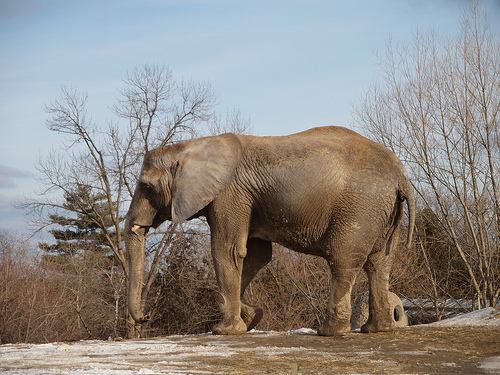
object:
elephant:
[123, 125, 416, 336]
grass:
[285, 341, 356, 368]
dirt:
[170, 335, 250, 350]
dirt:
[26, 341, 76, 360]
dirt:
[137, 353, 215, 374]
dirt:
[227, 337, 319, 369]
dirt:
[306, 349, 370, 369]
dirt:
[205, 353, 297, 371]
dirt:
[57, 340, 121, 350]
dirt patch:
[423, 333, 489, 354]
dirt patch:
[154, 363, 194, 367]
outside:
[1, 0, 500, 375]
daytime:
[283, 1, 413, 27]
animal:
[123, 125, 414, 337]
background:
[0, 59, 500, 346]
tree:
[9, 60, 222, 339]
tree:
[344, 0, 500, 309]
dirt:
[397, 327, 500, 338]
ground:
[0, 307, 498, 374]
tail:
[398, 170, 416, 249]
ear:
[171, 132, 243, 223]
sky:
[1, 0, 500, 195]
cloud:
[187, 51, 262, 81]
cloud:
[0, 164, 29, 182]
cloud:
[0, 7, 69, 45]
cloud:
[6, 35, 54, 60]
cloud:
[257, 101, 327, 122]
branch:
[67, 252, 73, 259]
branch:
[40, 203, 57, 209]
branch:
[80, 205, 88, 214]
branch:
[85, 196, 94, 206]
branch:
[94, 242, 113, 251]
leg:
[206, 214, 247, 335]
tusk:
[131, 225, 140, 232]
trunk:
[123, 216, 151, 324]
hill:
[411, 307, 494, 327]